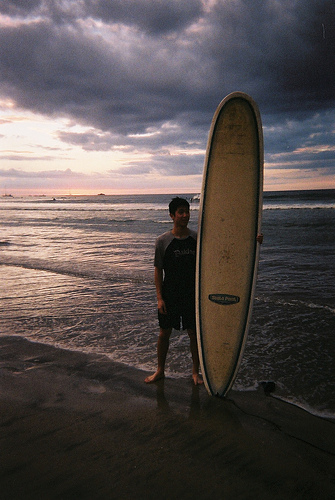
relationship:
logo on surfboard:
[210, 289, 241, 303] [198, 89, 259, 392]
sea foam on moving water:
[15, 308, 286, 390] [2, 185, 334, 415]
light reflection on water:
[0, 261, 97, 317] [1, 193, 331, 349]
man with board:
[152, 191, 205, 392] [194, 88, 265, 397]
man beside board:
[152, 191, 205, 392] [194, 88, 265, 397]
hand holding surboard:
[135, 84, 266, 405] [191, 87, 261, 366]